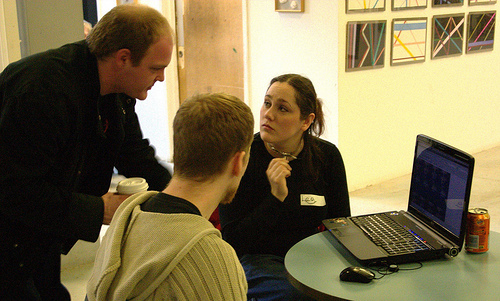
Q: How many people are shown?
A: Three.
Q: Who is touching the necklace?
A: The woman.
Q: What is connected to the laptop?
A: The mouse.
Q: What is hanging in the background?
A: Abstract art.